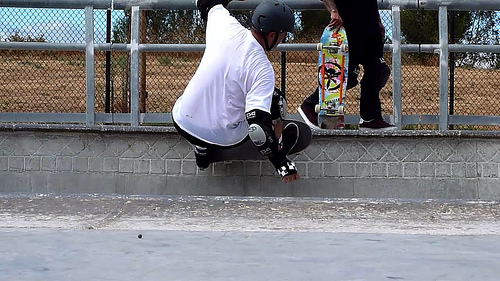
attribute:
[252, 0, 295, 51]
helmet — black, matte black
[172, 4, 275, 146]
shirt — white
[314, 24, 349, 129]
skateboard — multicolored, colorful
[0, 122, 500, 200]
wall — small, concrete, low, gray, cement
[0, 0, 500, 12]
railing — metal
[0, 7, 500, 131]
fence — chain link, metal, black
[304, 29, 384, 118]
pants — black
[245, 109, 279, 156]
elbow pad — black, gray, silver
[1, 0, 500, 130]
railing — silver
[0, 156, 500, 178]
row of squares — decorative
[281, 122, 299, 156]
shoe — black, white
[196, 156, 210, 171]
shoe — black, white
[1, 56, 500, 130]
field — brown, grassy, gold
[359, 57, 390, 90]
kneed pad — black, safety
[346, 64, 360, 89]
kneed pad — black, safety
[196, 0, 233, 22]
elbow pad — silver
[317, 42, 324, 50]
wheel — white, polyurethane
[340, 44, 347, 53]
wheel — white, polyurethane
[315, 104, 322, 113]
wheel — white, polyurethane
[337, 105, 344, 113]
wheel — white, polyurethane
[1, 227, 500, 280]
ground — gray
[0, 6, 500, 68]
sky — blue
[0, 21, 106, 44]
cloudy area — white, distant